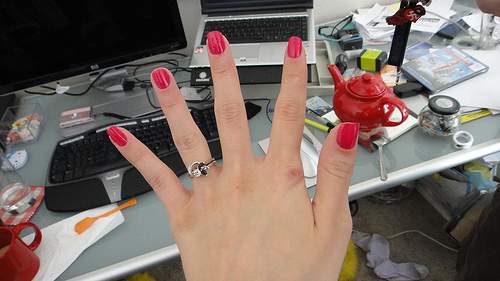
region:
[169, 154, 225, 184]
ring is on her finger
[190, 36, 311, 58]
the nails are red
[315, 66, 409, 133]
the kettle is red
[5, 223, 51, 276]
the cup has tea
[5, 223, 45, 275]
the cup is red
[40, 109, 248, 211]
the keyboard is black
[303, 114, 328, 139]
the pen is yellow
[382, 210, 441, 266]
the floor is carpeted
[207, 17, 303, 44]
the keys are black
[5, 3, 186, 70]
the tv is off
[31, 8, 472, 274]
woman's hand near desk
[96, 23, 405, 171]
fingernails polished pink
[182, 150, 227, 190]
ring is black and white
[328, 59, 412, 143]
red porcelain tea kettle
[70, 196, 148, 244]
orange plastic utensil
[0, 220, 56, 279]
coffee in red mug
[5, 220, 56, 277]
ceramic coffee mug is red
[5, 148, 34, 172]
Hello Kitty note pad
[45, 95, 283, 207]
computer keyboard on desk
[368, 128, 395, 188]
silver spoon next to tea kettle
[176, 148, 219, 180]
A silver ring on the finger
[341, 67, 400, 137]
A red teapoton the table.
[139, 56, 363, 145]
Finger nails are polished red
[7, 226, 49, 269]
Red coffee cup on the table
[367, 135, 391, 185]
Silver spoon next to the teapot.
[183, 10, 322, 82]
A laptop on the desk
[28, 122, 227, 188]
A black keyboard on the desk.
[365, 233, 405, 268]
White socks on the floor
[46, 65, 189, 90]
Wires behind the monitor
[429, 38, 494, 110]
Paper on the desk.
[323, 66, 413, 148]
A red teapot on the desk.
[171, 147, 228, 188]
A silver ring on the person finger.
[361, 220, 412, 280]
White dirty socks on the floor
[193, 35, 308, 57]
Finger nails are polished.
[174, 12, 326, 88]
Laptop on the desk.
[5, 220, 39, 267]
Red coffee mug on the table.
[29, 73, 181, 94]
Black cords behind the monitor.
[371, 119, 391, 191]
A small on the desk.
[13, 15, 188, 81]
A black monitor on the desk.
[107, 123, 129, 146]
the pink polished nail on a hand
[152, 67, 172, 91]
the pink polished nail on a hand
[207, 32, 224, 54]
the pink polished nail on a hand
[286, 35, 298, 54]
the pink polished nail on a hand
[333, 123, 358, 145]
the pink polished nail on a hand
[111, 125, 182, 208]
the long finger of a hand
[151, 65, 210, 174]
the long finger of a hand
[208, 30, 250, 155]
the long finger of a hand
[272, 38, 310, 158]
the long finger of a hand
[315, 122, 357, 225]
the thumb of a hand